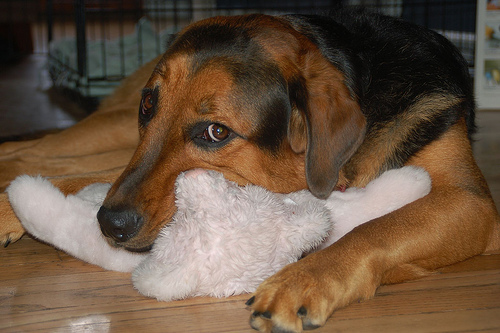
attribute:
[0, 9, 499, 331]
dog — large, lying down, brown, black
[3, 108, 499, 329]
floor — wood, brown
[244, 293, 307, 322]
claws — black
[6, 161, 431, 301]
teddy bear — pink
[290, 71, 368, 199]
ear — brown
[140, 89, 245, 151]
eyes — brown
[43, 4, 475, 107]
cage — black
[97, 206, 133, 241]
nose — black